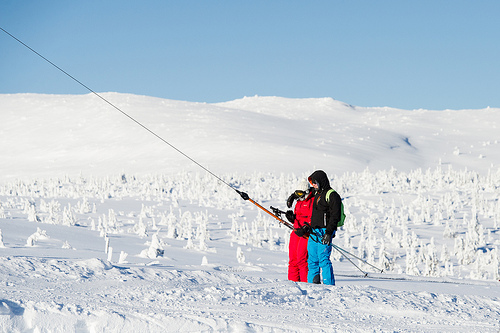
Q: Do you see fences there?
A: No, there are no fences.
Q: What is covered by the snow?
A: The ground is covered by the snow.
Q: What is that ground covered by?
A: The ground is covered by the snow.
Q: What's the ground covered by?
A: The ground is covered by the snow.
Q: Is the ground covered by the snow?
A: Yes, the ground is covered by the snow.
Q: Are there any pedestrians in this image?
A: No, there are no pedestrians.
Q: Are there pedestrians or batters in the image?
A: No, there are no pedestrians or batters.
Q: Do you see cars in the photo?
A: No, there are no cars.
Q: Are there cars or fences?
A: No, there are no cars or fences.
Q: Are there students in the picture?
A: No, there are no students.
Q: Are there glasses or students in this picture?
A: No, there are no students or glasses.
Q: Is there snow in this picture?
A: Yes, there is snow.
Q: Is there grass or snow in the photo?
A: Yes, there is snow.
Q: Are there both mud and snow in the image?
A: No, there is snow but no mud.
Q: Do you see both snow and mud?
A: No, there is snow but no mud.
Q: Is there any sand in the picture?
A: No, there is no sand.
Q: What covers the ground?
A: The snow covers the ground.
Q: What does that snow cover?
A: The snow covers the ground.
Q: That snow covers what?
A: The snow covers the ground.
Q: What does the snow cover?
A: The snow covers the ground.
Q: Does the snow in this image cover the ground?
A: Yes, the snow covers the ground.